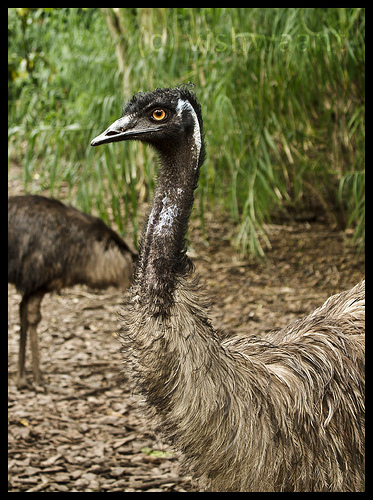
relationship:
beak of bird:
[89, 113, 150, 144] [88, 84, 367, 493]